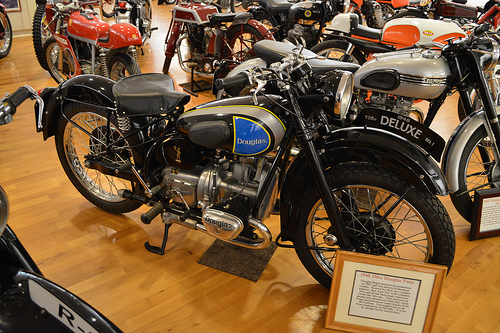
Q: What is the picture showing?
A: It is showing a display.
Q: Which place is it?
A: It is a display.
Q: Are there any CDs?
A: No, there are no cds.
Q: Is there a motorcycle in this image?
A: Yes, there is a motorcycle.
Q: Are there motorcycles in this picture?
A: Yes, there is a motorcycle.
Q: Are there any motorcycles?
A: Yes, there is a motorcycle.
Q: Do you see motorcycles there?
A: Yes, there is a motorcycle.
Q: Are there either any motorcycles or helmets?
A: Yes, there is a motorcycle.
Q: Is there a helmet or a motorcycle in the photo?
A: Yes, there is a motorcycle.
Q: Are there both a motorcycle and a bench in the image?
A: No, there is a motorcycle but no benches.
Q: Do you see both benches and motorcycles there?
A: No, there is a motorcycle but no benches.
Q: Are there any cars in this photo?
A: No, there are no cars.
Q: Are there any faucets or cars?
A: No, there are no cars or faucets.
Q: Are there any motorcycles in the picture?
A: Yes, there is a motorcycle.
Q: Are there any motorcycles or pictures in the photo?
A: Yes, there is a motorcycle.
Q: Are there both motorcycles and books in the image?
A: No, there is a motorcycle but no books.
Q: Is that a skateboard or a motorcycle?
A: That is a motorcycle.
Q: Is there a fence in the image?
A: No, there are no fences.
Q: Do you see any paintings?
A: No, there are no paintings.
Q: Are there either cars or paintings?
A: No, there are no paintings or cars.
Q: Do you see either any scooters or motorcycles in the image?
A: Yes, there are motorcycles.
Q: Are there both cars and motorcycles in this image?
A: No, there are motorcycles but no cars.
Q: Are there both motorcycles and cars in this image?
A: No, there are motorcycles but no cars.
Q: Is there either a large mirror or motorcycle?
A: Yes, there are large motorcycles.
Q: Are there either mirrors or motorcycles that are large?
A: Yes, the motorcycles are large.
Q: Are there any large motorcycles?
A: Yes, there are large motorcycles.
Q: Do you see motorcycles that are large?
A: Yes, there are large motorcycles.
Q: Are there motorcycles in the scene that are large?
A: Yes, there are motorcycles that are large.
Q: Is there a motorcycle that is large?
A: Yes, there are motorcycles that are large.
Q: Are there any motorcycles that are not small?
A: Yes, there are large motorcycles.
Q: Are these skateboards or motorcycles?
A: These are motorcycles.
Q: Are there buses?
A: No, there are no buses.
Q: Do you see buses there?
A: No, there are no buses.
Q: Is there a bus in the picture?
A: No, there are no buses.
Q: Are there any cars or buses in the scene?
A: No, there are no buses or cars.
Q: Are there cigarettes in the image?
A: No, there are no cigarettes.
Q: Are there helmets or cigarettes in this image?
A: No, there are no cigarettes or helmets.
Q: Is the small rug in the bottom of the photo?
A: Yes, the rug is in the bottom of the image.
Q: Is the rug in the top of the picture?
A: No, the rug is in the bottom of the image.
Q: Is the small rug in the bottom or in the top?
A: The rug is in the bottom of the image.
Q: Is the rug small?
A: Yes, the rug is small.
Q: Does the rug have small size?
A: Yes, the rug is small.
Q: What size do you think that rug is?
A: The rug is small.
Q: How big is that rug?
A: The rug is small.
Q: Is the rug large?
A: No, the rug is small.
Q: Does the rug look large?
A: No, the rug is small.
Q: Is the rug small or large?
A: The rug is small.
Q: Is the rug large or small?
A: The rug is small.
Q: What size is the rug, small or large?
A: The rug is small.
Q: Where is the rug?
A: The rug is on the ground.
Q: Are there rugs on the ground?
A: Yes, there is a rug on the ground.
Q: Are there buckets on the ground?
A: No, there is a rug on the ground.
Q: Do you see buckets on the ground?
A: No, there is a rug on the ground.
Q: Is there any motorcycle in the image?
A: Yes, there is a motorcycle.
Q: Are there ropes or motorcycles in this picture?
A: Yes, there is a motorcycle.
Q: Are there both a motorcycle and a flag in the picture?
A: No, there is a motorcycle but no flags.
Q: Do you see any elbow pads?
A: No, there are no elbow pads.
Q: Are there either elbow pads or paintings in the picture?
A: No, there are no elbow pads or paintings.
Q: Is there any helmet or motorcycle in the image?
A: Yes, there is a motorcycle.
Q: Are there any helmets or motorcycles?
A: Yes, there is a motorcycle.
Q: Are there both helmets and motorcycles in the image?
A: No, there is a motorcycle but no helmets.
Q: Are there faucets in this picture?
A: No, there are no faucets.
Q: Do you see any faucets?
A: No, there are no faucets.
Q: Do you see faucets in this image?
A: No, there are no faucets.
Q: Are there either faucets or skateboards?
A: No, there are no faucets or skateboards.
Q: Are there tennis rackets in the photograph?
A: No, there are no tennis rackets.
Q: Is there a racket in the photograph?
A: No, there are no rackets.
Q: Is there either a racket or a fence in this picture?
A: No, there are no rackets or fences.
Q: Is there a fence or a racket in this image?
A: No, there are no rackets or fences.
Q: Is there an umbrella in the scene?
A: No, there are no umbrellas.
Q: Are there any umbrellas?
A: No, there are no umbrellas.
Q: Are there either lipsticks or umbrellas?
A: No, there are no umbrellas or lipsticks.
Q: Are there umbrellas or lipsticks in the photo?
A: No, there are no umbrellas or lipsticks.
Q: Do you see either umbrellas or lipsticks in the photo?
A: No, there are no umbrellas or lipsticks.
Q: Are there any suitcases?
A: No, there are no suitcases.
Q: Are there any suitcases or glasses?
A: No, there are no suitcases or glasses.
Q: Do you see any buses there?
A: No, there are no buses.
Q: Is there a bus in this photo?
A: No, there are no buses.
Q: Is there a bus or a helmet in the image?
A: No, there are no buses or helmets.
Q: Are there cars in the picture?
A: No, there are no cars.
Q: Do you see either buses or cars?
A: No, there are no cars or buses.